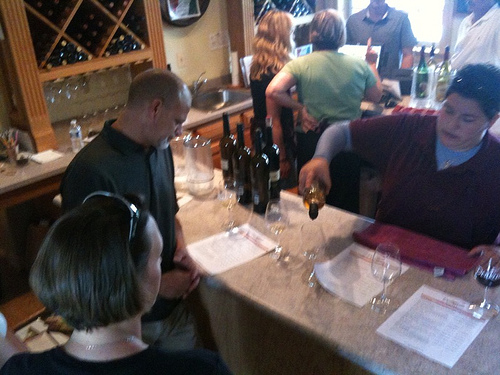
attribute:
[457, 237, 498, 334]
wine — red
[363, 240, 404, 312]
glass — empty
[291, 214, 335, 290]
glass — empty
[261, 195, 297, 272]
glass — empty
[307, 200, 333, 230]
tip — Black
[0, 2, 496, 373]
people — tasting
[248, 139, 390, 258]
wine — poured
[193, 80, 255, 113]
sink — metal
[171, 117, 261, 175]
container — large, glass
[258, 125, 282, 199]
botles — several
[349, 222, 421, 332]
glass — wine glass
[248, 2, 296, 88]
blonde hair — wavy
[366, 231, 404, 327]
glass — empty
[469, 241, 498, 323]
glass — empty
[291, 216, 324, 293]
glass — empty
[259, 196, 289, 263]
glass — empty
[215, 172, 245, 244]
glass — empty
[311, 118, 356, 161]
undershirt — grey 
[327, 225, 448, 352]
wine glass — empty